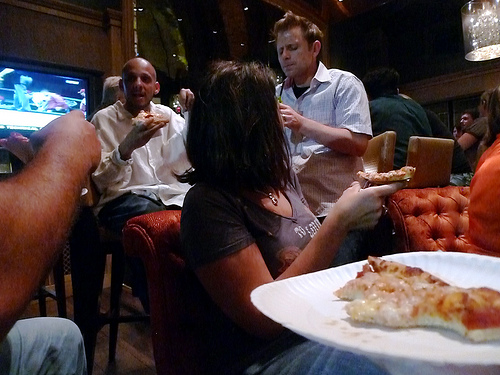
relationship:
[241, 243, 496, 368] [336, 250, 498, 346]
white plate with pizza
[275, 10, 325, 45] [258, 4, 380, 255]
hair on man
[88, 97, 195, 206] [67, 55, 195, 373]
shirt on man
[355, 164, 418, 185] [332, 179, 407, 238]
pizza in hand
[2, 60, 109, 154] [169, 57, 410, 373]
tv behind woman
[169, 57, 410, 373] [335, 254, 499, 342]
woman eating pizza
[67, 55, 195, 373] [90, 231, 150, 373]
man sitting on stool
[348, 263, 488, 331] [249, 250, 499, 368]
pizza on white plate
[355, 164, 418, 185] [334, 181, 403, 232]
pizza in hand